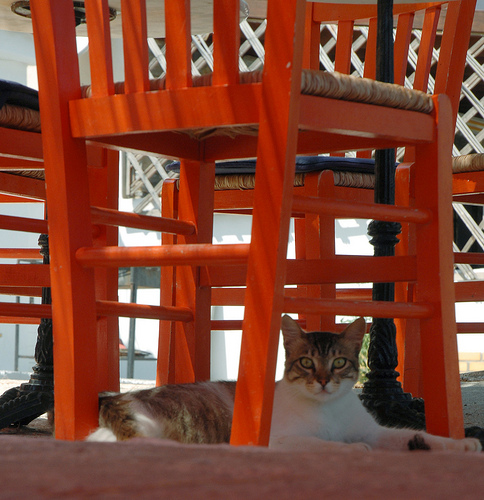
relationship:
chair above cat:
[27, 2, 477, 447] [85, 313, 482, 454]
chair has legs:
[27, 2, 477, 447] [42, 124, 466, 448]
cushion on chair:
[77, 66, 435, 108] [27, 2, 477, 447]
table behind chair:
[0, 0, 481, 447] [27, 2, 477, 447]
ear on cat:
[340, 316, 366, 355] [85, 313, 482, 454]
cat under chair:
[85, 313, 482, 454] [27, 2, 477, 447]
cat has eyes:
[85, 313, 482, 454] [299, 357, 348, 369]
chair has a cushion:
[27, 2, 477, 447] [77, 66, 435, 108]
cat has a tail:
[85, 313, 482, 454] [97, 395, 142, 442]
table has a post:
[0, 0, 481, 447] [0, 0, 484, 451]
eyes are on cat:
[299, 357, 348, 369] [85, 313, 482, 454]